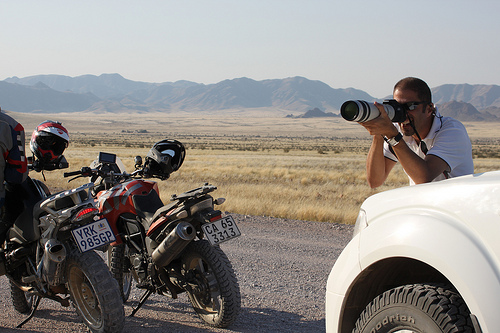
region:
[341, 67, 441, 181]
hes holding a camera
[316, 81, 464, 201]
He's taking a picture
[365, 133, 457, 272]
leaning on a white car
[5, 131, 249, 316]
Two motorcycles next to eachother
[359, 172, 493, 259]
the car is white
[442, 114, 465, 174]
the shirt is white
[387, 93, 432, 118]
He is wearing glasses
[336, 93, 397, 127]
his camera is white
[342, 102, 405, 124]
His camera is long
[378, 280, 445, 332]
the tire is made of rubber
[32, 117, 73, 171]
red and white helmet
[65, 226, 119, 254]
black and white license plate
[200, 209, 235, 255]
license plate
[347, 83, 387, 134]
black and silver camera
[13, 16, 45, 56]
white clouds in blue sky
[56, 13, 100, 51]
white clouds in blue sky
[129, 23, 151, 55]
white clouds in blue sky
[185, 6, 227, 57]
white clouds in blue sky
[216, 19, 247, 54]
white clouds in blue sky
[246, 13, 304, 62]
white clouds in blue sky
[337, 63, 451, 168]
a man with a camera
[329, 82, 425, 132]
a very big canera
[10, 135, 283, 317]
two motorcycles side by side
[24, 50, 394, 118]
mountains in the back ground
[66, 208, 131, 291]
a license plate on a motor cycle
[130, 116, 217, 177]
a helmet on a motorcycle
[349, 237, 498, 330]
the front wheel on a truck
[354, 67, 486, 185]
a man with a white shirt on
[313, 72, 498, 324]
a man leaning on a white truck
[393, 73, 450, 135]
a man wearing sunglasses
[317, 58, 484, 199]
person holding camera up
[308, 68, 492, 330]
person standing in front of car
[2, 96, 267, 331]
two motorcycles parked next to each other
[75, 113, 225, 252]
motorcycle has helmet on it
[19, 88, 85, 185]
helmet is red and silver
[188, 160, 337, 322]
road is made of gravel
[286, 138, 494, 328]
car is white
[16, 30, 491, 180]
mountains line back ground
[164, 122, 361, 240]
grass is dry and yellow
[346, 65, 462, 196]
person has watch on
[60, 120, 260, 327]
bike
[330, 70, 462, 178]
man taking picture with camera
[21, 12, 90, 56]
white clouds in blue sky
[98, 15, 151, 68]
white clouds in blue sky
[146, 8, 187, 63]
white clouds in blue sky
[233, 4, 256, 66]
white clouds in blue sky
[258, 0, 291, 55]
white clouds in blue sky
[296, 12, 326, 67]
white clouds in blue sky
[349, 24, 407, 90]
white clouds in blue sky